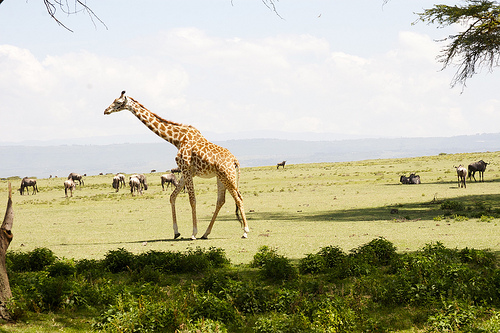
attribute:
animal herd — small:
[8, 157, 491, 197]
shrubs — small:
[2, 237, 499, 331]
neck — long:
[127, 102, 190, 144]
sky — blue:
[0, 0, 499, 177]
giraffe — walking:
[101, 88, 252, 241]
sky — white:
[273, 48, 420, 137]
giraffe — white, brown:
[86, 70, 328, 290]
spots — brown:
[174, 133, 214, 163]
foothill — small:
[330, 171, 425, 201]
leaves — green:
[409, 2, 498, 92]